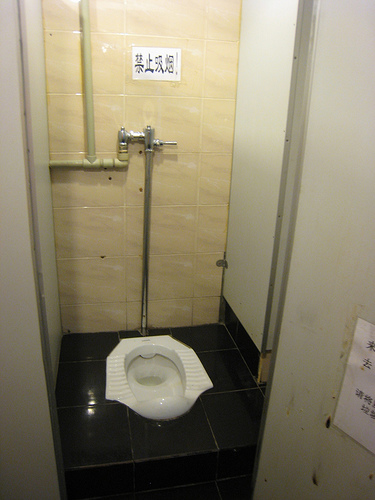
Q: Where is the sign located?
A: On the wall.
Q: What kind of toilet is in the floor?
A: A squat toilet.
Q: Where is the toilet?
A: On a black tile floor.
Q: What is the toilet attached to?
A: Exposed plumbing.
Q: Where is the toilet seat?
A: Down.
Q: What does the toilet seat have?
A: It has ridges.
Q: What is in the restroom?
A: A stall.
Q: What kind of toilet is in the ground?
A: A white porcelain toilet.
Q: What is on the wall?
A: Pipe for toilet.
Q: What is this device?
A: A toilet.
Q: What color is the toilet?
A: White.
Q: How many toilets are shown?
A: One.